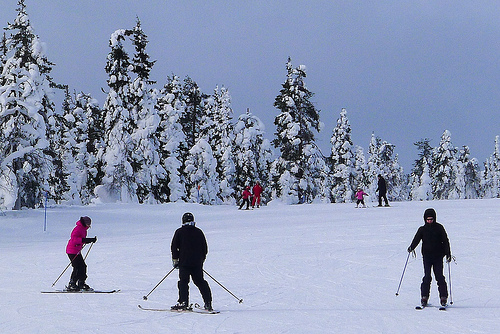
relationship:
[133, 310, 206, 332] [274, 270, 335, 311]
tracks in snow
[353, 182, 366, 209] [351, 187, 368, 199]
child wearing jacket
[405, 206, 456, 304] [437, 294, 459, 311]
person on ski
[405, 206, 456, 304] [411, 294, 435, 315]
person on ski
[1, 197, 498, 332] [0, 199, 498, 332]
plain of snow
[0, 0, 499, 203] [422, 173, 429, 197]
trees covered in snow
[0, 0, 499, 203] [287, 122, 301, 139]
trees covered in snow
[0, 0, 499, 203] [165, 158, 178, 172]
trees covered in snow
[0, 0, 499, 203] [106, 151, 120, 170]
trees covered in snow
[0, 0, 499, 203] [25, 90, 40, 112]
trees covered in snow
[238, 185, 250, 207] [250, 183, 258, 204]
skier in outfit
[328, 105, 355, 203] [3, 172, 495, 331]
tree in snow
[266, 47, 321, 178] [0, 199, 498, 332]
tree covered in snow